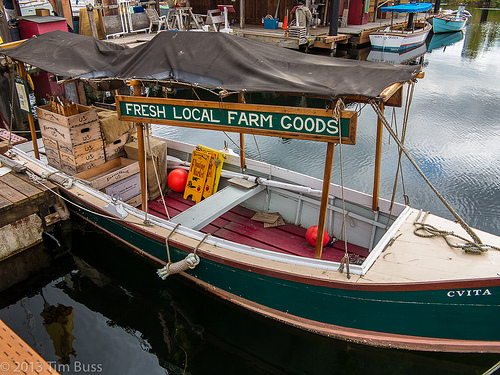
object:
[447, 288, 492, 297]
name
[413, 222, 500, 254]
bow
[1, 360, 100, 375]
owner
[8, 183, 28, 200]
dock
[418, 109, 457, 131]
water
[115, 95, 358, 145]
advertisement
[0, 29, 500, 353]
boat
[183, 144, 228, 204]
bumper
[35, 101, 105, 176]
crates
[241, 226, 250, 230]
deck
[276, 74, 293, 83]
tarp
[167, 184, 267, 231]
bench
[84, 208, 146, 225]
ropes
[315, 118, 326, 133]
sign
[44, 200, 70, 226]
steps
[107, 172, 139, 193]
planks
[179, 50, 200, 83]
roof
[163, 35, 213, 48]
tent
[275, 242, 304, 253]
floor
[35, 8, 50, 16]
chairs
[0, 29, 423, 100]
canopy